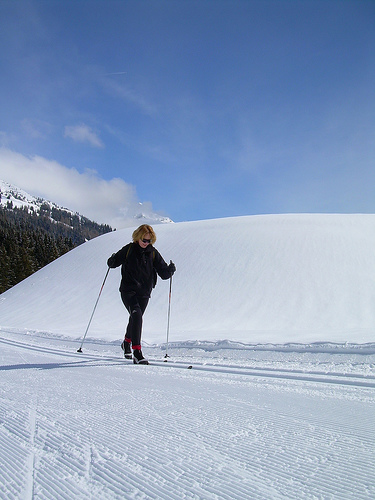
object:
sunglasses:
[142, 238, 153, 242]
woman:
[107, 222, 176, 367]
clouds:
[0, 115, 147, 229]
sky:
[3, 2, 374, 212]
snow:
[1, 207, 370, 495]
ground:
[1, 342, 371, 494]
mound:
[4, 214, 372, 333]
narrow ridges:
[15, 368, 330, 496]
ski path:
[1, 340, 372, 496]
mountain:
[1, 184, 111, 283]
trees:
[1, 222, 25, 277]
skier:
[98, 223, 178, 364]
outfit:
[103, 240, 177, 372]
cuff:
[132, 342, 141, 349]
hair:
[130, 223, 158, 244]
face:
[140, 234, 151, 248]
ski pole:
[164, 277, 173, 357]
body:
[114, 246, 164, 344]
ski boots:
[121, 341, 133, 360]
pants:
[114, 296, 154, 354]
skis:
[98, 358, 191, 370]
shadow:
[0, 353, 139, 372]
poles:
[74, 273, 109, 353]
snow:
[5, 176, 54, 212]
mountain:
[0, 220, 374, 332]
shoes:
[133, 349, 150, 365]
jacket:
[102, 241, 174, 300]